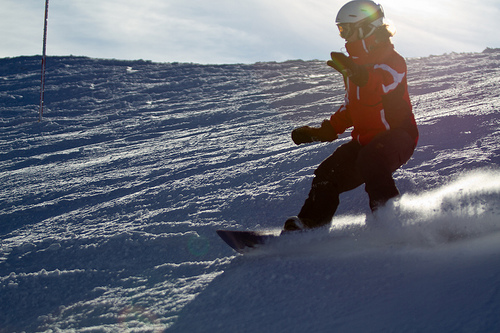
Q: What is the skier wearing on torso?
A: Red jacket.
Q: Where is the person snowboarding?
A: Snowy slope.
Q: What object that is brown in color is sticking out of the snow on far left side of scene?
A: Pole.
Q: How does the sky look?
A: It looks light blue and cloudy.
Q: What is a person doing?
A: Snow boarding.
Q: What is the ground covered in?
A: Snow.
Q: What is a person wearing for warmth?
A: A red and white jacket.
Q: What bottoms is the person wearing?
A: Black pants.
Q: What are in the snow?
A: Tracks.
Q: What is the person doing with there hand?
A: Holding it out.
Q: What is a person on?
A: A snow board.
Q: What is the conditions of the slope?
A: Snowy.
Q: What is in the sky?
A: Cloud cover.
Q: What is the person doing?
A: Snowboarding.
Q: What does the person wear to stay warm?
A: Snow pants and a heavy coat.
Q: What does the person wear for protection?
A: A helmet.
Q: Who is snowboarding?
A: A person in a red coat.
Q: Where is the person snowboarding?
A: On a hill.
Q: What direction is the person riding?
A: Riding downhill.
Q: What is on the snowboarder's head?
A: A helmet.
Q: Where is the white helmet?
A: On the person's head.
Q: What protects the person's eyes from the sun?
A: The goggles.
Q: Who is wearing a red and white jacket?
A: The snowboarder.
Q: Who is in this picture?
A: A snowboarder.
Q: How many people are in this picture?
A: One.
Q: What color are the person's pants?
A: Black.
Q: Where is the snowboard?
A: Under the person.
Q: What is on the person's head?
A: A helmet.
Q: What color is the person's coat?
A: Red.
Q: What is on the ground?
A: Snow.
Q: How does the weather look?
A: Sunny.